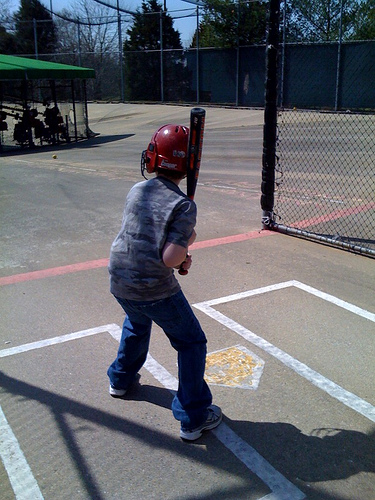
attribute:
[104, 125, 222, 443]
boy — playing baseball, getting ready, learning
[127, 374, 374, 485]
shadow — grey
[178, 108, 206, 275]
bat — multi-colored, upright, baseball bat, black color, black, red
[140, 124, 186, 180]
helmet — painted red, red, colored red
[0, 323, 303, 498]
lines — batter box, white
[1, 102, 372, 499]
ground — grey color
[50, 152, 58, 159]
ball — yellow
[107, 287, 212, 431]
jeans — blue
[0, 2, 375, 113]
fence — chain link, grey color, to right, grey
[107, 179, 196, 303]
shirt — grey, camo, short-sleeved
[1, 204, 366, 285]
line — red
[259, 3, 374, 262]
net — for batting cage, black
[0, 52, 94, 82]
roof — tent, green color, tent canopy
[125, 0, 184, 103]
tree — green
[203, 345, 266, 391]
home base plate — yellow, white